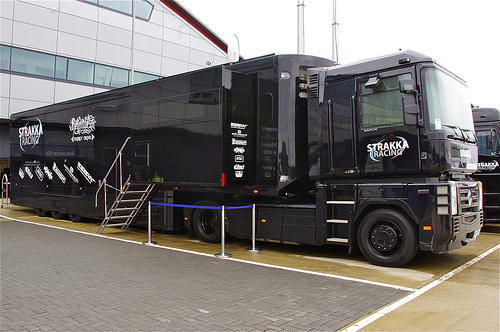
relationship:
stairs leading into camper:
[94, 136, 156, 234] [1, 50, 482, 239]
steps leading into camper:
[324, 183, 356, 249] [1, 50, 482, 239]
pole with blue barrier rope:
[221, 205, 226, 257] [150, 199, 253, 213]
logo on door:
[358, 132, 411, 162] [351, 65, 421, 174]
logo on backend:
[14, 118, 46, 150] [7, 90, 126, 223]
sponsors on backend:
[8, 103, 105, 188] [7, 90, 126, 223]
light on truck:
[420, 220, 433, 233] [6, 47, 484, 261]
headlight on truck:
[448, 181, 459, 211] [8, 45, 485, 241]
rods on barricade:
[143, 203, 263, 259] [133, 188, 263, 264]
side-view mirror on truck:
[400, 87, 419, 126] [6, 47, 484, 261]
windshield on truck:
[418, 70, 476, 134] [6, 47, 484, 261]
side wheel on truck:
[181, 189, 228, 246] [8, 45, 485, 241]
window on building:
[9, 42, 58, 79] [2, 1, 236, 125]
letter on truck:
[366, 136, 410, 162] [6, 47, 484, 261]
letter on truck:
[366, 136, 410, 162] [8, 45, 485, 241]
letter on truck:
[397, 138, 405, 154] [8, 45, 485, 241]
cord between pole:
[149, 199, 221, 210] [140, 197, 160, 247]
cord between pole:
[149, 199, 221, 210] [215, 205, 232, 259]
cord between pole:
[222, 202, 252, 217] [215, 205, 232, 259]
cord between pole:
[149, 199, 221, 210] [245, 202, 263, 255]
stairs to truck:
[94, 136, 156, 234] [3, 39, 483, 275]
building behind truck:
[0, 2, 244, 169] [6, 47, 484, 261]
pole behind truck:
[293, 1, 312, 55] [6, 47, 484, 261]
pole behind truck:
[327, 1, 342, 59] [6, 47, 484, 261]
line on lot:
[332, 259, 483, 329] [2, 200, 483, 329]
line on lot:
[2, 213, 413, 293] [2, 200, 483, 329]